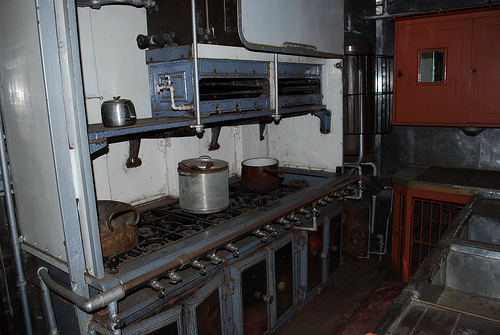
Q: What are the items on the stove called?
A: Pots.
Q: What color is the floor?
A: Brown.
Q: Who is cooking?
A: No one.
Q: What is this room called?
A: Kitchen.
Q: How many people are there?
A: None.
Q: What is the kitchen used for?
A: Preparing meals.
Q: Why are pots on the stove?
A: To heat them.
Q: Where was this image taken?
A: In a kitchen.